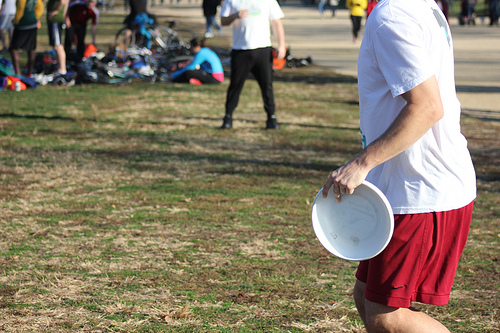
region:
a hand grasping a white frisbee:
[303, 177, 387, 197]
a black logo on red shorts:
[385, 274, 407, 295]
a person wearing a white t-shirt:
[332, 5, 477, 313]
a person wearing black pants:
[216, 2, 293, 137]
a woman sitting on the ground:
[170, 37, 222, 82]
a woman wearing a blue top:
[164, 32, 229, 97]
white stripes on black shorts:
[49, 22, 62, 45]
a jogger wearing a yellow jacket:
[344, 5, 365, 42]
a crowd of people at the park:
[8, 3, 221, 99]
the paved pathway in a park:
[309, 20, 341, 52]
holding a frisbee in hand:
[256, 136, 426, 276]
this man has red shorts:
[261, 136, 464, 318]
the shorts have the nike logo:
[289, 136, 460, 329]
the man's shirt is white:
[281, 6, 481, 208]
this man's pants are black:
[202, 7, 299, 187]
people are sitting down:
[85, 36, 239, 134]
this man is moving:
[207, 6, 497, 288]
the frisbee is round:
[281, 97, 416, 291]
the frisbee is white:
[282, 136, 444, 270]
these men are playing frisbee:
[205, 5, 492, 287]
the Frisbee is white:
[268, 170, 411, 301]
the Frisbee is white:
[323, 177, 381, 298]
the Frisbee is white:
[292, 135, 375, 325]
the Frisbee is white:
[341, 144, 390, 331]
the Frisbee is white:
[308, 174, 360, 325]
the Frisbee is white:
[315, 95, 413, 306]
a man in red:
[341, 158, 481, 318]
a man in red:
[281, 85, 369, 290]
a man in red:
[303, 218, 385, 322]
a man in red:
[333, 178, 403, 293]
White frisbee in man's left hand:
[302, 171, 401, 261]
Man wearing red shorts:
[348, 210, 468, 304]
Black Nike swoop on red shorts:
[388, 281, 410, 291]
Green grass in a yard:
[198, 181, 274, 210]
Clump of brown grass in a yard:
[27, 274, 96, 331]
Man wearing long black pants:
[213, 46, 291, 114]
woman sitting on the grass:
[172, 36, 224, 91]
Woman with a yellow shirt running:
[344, 2, 364, 39]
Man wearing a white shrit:
[341, 0, 482, 210]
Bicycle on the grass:
[113, 8, 200, 51]